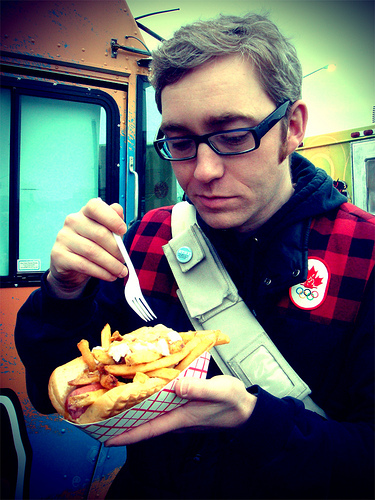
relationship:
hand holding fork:
[49, 195, 129, 287] [93, 196, 159, 322]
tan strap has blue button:
[164, 249, 303, 399] [170, 237, 191, 264]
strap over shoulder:
[160, 200, 325, 415] [121, 202, 202, 283]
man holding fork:
[14, 9, 375, 500] [111, 230, 156, 320]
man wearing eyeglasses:
[14, 9, 375, 500] [152, 100, 292, 165]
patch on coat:
[288, 253, 330, 310] [12, 151, 375, 500]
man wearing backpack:
[3, 19, 366, 372] [156, 190, 320, 365]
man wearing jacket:
[14, 9, 375, 500] [9, 158, 361, 478]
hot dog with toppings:
[64, 383, 105, 418] [75, 324, 179, 383]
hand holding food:
[103, 374, 256, 451] [36, 292, 263, 436]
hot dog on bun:
[54, 328, 155, 444] [46, 340, 178, 411]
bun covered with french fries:
[46, 340, 178, 411] [77, 321, 216, 375]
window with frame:
[2, 70, 126, 292] [11, 71, 124, 296]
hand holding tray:
[103, 374, 256, 451] [60, 345, 210, 444]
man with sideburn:
[14, 9, 375, 500] [276, 106, 288, 163]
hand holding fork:
[47, 195, 129, 288] [113, 229, 158, 321]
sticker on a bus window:
[16, 258, 42, 270] [19, 91, 110, 273]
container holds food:
[37, 99, 309, 463] [47, 323, 230, 423]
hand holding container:
[103, 391, 255, 451] [58, 336, 210, 444]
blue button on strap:
[176, 245, 191, 264] [160, 200, 325, 415]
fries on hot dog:
[40, 320, 228, 428] [55, 375, 103, 421]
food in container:
[99, 343, 166, 405] [58, 336, 210, 444]